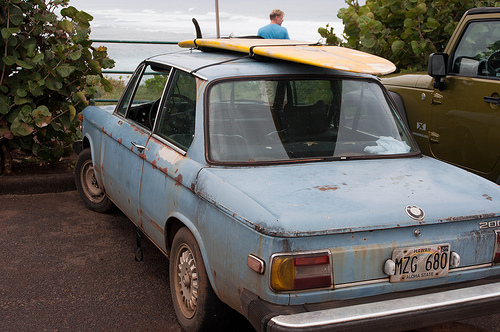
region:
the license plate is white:
[391, 251, 452, 278]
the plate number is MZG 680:
[389, 244, 455, 282]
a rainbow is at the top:
[399, 244, 450, 264]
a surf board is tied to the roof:
[180, 11, 406, 86]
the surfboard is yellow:
[178, 13, 408, 83]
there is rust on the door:
[110, 111, 190, 226]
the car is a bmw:
[71, 41, 498, 329]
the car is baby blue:
[64, 34, 496, 329]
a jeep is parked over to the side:
[371, 4, 494, 188]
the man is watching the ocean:
[248, 5, 291, 37]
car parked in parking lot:
[71, 2, 408, 327]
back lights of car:
[247, 247, 328, 301]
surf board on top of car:
[95, 4, 383, 159]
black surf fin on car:
[151, 11, 229, 56]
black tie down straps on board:
[235, 30, 345, 71]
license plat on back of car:
[371, 234, 466, 298]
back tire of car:
[121, 217, 222, 304]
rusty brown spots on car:
[54, 81, 189, 285]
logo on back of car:
[330, 198, 428, 243]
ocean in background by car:
[68, 14, 263, 89]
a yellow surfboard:
[168, 7, 398, 82]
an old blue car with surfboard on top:
[75, 25, 495, 322]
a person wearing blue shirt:
[251, 1, 293, 36]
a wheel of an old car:
[149, 203, 226, 330]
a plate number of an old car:
[380, 242, 464, 282]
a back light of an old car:
[268, 248, 339, 297]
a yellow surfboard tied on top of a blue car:
[69, 0, 497, 322]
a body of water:
[97, 8, 155, 33]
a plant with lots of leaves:
[9, 5, 76, 150]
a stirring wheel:
[143, 90, 188, 130]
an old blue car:
[50, 55, 494, 328]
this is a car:
[66, 22, 498, 329]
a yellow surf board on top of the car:
[164, 16, 416, 88]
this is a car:
[375, 0, 495, 181]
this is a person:
[250, 0, 300, 51]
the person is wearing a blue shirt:
[256, 10, 291, 40]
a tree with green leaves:
[0, 0, 113, 155]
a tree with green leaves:
[323, 0, 498, 71]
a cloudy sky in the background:
[70, 1, 370, 94]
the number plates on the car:
[386, 246, 457, 291]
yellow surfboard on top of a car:
[177, 8, 400, 76]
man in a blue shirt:
[257, 7, 290, 36]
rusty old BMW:
[71, 46, 498, 330]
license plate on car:
[385, 240, 455, 285]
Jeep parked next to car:
[376, 2, 498, 172]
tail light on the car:
[264, 245, 338, 299]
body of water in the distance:
[90, 33, 185, 70]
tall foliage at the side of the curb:
[2, 0, 119, 179]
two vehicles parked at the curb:
[66, 1, 496, 328]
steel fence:
[74, 37, 180, 105]